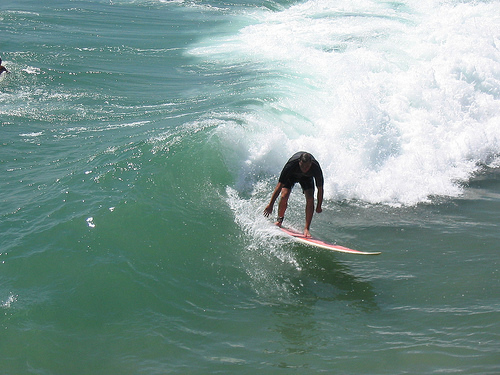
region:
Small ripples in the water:
[17, 262, 79, 308]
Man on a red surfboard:
[251, 117, 385, 263]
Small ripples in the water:
[142, 298, 227, 341]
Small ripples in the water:
[255, 282, 312, 341]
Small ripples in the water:
[340, 308, 432, 367]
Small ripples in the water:
[430, 290, 463, 353]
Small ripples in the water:
[341, 257, 432, 291]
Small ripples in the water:
[442, 232, 489, 282]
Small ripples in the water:
[338, 200, 435, 241]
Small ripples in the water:
[82, 132, 177, 199]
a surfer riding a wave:
[207, 98, 405, 283]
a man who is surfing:
[232, 122, 412, 283]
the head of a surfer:
[293, 148, 316, 176]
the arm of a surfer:
[258, 178, 280, 220]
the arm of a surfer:
[314, 169, 326, 219]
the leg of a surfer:
[299, 183, 316, 240]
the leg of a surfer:
[273, 181, 290, 227]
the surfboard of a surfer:
[250, 225, 384, 256]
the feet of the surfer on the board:
[268, 216, 320, 243]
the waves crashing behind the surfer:
[274, 58, 497, 177]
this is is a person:
[264, 133, 339, 230]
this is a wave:
[260, 133, 387, 181]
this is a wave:
[345, 145, 430, 245]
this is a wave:
[208, 105, 272, 170]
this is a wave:
[315, 98, 366, 175]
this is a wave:
[382, 86, 446, 184]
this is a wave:
[251, 46, 359, 160]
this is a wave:
[392, 52, 476, 149]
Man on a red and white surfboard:
[228, 124, 390, 273]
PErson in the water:
[0, 51, 13, 79]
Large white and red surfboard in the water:
[262, 213, 375, 263]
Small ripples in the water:
[44, 219, 88, 280]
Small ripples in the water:
[46, 165, 81, 210]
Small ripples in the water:
[66, 135, 127, 195]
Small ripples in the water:
[110, 102, 210, 194]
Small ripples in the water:
[219, 33, 304, 95]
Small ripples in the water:
[114, 29, 189, 65]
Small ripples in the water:
[27, 26, 117, 87]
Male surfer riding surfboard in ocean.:
[263, 150, 382, 257]